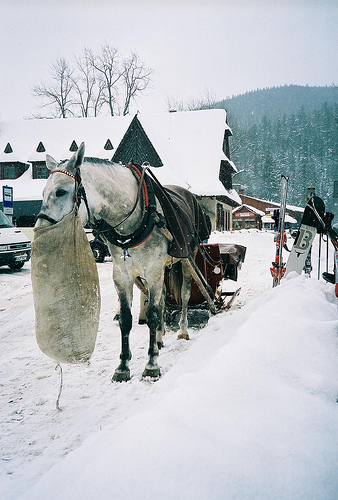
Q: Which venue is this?
A: This is a street.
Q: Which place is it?
A: It is a street.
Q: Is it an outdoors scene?
A: Yes, it is outdoors.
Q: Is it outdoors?
A: Yes, it is outdoors.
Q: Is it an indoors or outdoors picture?
A: It is outdoors.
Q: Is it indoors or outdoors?
A: It is outdoors.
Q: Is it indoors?
A: No, it is outdoors.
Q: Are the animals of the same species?
A: Yes, all the animals are horses.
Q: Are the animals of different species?
A: No, all the animals are horses.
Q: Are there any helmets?
A: No, there are no helmets.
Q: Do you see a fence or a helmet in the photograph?
A: No, there are no helmets or fences.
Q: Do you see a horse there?
A: Yes, there is a horse.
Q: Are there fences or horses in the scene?
A: Yes, there is a horse.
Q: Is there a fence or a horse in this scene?
A: Yes, there is a horse.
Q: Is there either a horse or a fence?
A: Yes, there is a horse.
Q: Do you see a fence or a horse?
A: Yes, there is a horse.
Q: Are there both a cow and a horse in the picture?
A: No, there is a horse but no cows.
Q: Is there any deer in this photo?
A: No, there is no deer.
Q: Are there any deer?
A: No, there are no deer.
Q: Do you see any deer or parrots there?
A: No, there are no deer or parrots.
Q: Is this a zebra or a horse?
A: This is a horse.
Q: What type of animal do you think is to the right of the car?
A: The animal is a horse.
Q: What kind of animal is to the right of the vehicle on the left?
A: The animal is a horse.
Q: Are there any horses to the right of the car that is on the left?
A: Yes, there is a horse to the right of the car.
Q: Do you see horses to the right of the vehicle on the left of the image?
A: Yes, there is a horse to the right of the car.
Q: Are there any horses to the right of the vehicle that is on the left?
A: Yes, there is a horse to the right of the car.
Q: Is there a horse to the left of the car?
A: No, the horse is to the right of the car.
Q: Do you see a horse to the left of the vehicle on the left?
A: No, the horse is to the right of the car.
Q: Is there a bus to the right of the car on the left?
A: No, there is a horse to the right of the car.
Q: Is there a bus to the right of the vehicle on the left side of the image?
A: No, there is a horse to the right of the car.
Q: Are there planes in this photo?
A: No, there are no planes.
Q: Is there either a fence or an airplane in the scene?
A: No, there are no airplanes or fences.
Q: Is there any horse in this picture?
A: Yes, there is a horse.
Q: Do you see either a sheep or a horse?
A: Yes, there is a horse.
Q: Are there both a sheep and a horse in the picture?
A: No, there is a horse but no sheep.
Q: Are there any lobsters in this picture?
A: No, there are no lobsters.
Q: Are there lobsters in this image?
A: No, there are no lobsters.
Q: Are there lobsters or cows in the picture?
A: No, there are no lobsters or cows.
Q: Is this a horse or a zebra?
A: This is a horse.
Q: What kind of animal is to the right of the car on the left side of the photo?
A: The animal is a horse.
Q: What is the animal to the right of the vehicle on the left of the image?
A: The animal is a horse.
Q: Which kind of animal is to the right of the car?
A: The animal is a horse.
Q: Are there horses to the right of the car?
A: Yes, there is a horse to the right of the car.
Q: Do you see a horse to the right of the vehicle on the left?
A: Yes, there is a horse to the right of the car.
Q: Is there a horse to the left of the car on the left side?
A: No, the horse is to the right of the car.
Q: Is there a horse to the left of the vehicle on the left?
A: No, the horse is to the right of the car.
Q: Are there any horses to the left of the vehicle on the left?
A: No, the horse is to the right of the car.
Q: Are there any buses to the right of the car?
A: No, there is a horse to the right of the car.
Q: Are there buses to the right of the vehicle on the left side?
A: No, there is a horse to the right of the car.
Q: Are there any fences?
A: No, there are no fences.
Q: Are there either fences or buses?
A: No, there are no fences or buses.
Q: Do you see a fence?
A: No, there are no fences.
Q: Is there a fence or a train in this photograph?
A: No, there are no fences or trains.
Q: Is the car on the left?
A: Yes, the car is on the left of the image.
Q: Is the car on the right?
A: No, the car is on the left of the image.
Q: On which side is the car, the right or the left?
A: The car is on the left of the image.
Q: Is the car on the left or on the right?
A: The car is on the left of the image.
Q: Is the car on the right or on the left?
A: The car is on the left of the image.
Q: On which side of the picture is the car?
A: The car is on the left of the image.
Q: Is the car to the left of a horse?
A: Yes, the car is to the left of a horse.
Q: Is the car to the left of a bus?
A: No, the car is to the left of a horse.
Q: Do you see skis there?
A: Yes, there are skis.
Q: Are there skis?
A: Yes, there are skis.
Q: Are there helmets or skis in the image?
A: Yes, there are skis.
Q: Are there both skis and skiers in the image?
A: No, there are skis but no skiers.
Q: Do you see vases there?
A: No, there are no vases.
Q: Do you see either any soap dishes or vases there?
A: No, there are no vases or soap dishes.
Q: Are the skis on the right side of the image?
A: Yes, the skis are on the right of the image.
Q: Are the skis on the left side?
A: No, the skis are on the right of the image.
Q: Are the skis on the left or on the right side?
A: The skis are on the right of the image.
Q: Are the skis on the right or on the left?
A: The skis are on the right of the image.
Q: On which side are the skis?
A: The skis are on the right of the image.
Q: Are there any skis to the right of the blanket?
A: Yes, there are skis to the right of the blanket.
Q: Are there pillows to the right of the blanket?
A: No, there are skis to the right of the blanket.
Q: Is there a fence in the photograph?
A: No, there are no fences.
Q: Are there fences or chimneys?
A: No, there are no fences or chimneys.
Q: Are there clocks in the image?
A: No, there are no clocks.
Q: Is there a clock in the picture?
A: No, there are no clocks.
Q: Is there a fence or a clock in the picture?
A: No, there are no clocks or fences.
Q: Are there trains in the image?
A: No, there are no trains.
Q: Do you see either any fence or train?
A: No, there are no trains or fences.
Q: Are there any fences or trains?
A: No, there are no trains or fences.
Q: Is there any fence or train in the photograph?
A: No, there are no trains or fences.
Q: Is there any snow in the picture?
A: Yes, there is snow.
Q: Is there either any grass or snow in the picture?
A: Yes, there is snow.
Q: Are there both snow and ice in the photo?
A: No, there is snow but no ice.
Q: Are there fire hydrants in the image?
A: No, there are no fire hydrants.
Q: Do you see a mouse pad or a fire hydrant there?
A: No, there are no fire hydrants or mouse pads.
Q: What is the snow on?
A: The snow is on the roof.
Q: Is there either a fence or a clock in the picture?
A: No, there are no fences or clocks.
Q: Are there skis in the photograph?
A: Yes, there are skis.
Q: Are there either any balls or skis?
A: Yes, there are skis.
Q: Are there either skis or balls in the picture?
A: Yes, there are skis.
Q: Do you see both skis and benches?
A: No, there are skis but no benches.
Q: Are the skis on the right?
A: Yes, the skis are on the right of the image.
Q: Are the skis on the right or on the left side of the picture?
A: The skis are on the right of the image.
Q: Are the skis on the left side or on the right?
A: The skis are on the right of the image.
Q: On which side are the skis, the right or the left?
A: The skis are on the right of the image.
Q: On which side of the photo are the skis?
A: The skis are on the right of the image.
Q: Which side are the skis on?
A: The skis are on the right of the image.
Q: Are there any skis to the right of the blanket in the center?
A: Yes, there are skis to the right of the blanket.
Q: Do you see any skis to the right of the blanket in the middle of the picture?
A: Yes, there are skis to the right of the blanket.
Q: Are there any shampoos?
A: No, there are no shampoos.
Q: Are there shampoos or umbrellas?
A: No, there are no shampoos or umbrellas.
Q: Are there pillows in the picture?
A: No, there are no pillows.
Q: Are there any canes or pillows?
A: No, there are no pillows or canes.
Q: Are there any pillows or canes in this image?
A: No, there are no pillows or canes.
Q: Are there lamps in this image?
A: No, there are no lamps.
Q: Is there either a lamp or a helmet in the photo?
A: No, there are no lamps or helmets.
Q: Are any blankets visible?
A: Yes, there is a blanket.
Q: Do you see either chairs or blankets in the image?
A: Yes, there is a blanket.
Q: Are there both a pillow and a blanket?
A: No, there is a blanket but no pillows.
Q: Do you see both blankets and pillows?
A: No, there is a blanket but no pillows.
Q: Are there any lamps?
A: No, there are no lamps.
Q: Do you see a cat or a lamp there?
A: No, there are no lamps or cats.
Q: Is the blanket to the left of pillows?
A: No, the blanket is to the left of the skis.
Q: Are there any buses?
A: No, there are no buses.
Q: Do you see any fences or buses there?
A: No, there are no buses or fences.